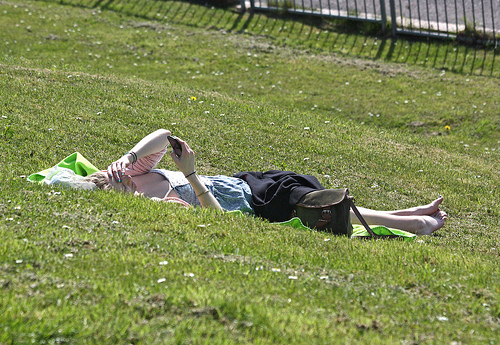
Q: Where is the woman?
A: Lying on grass.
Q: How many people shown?
A: 1.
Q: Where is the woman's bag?
A: Next to her.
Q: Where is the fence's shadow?
A: On the grass.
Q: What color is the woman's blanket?
A: Green.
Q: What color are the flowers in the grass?
A: White.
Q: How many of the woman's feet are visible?
A: 2.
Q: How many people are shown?
A: 1.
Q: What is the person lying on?
A: Grass.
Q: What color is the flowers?
A: White.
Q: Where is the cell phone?
A: Woman's right hand.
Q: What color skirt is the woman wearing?
A: Black.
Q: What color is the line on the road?
A: White.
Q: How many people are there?
A: 1.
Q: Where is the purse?
A: Next to the girl.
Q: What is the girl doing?
A: Laying in the grass.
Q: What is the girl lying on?
A: A blanket.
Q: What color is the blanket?
A: Green.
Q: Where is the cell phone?
A: In the girl's hands.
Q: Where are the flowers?
A: In the grass.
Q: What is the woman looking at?
A: Cellphone.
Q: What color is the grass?
A: Green.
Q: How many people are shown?
A: 1.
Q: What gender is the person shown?
A: Female.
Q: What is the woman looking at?
A: Cell phone.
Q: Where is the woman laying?
A: On ground.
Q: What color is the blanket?
A: Green.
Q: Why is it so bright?
A: Sun.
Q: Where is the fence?
A: By sidewalk.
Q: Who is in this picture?
A: A woman.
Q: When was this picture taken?
A: Daytime.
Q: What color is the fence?
A: Black.